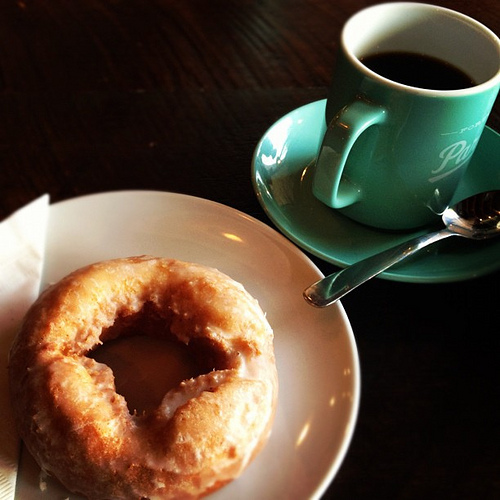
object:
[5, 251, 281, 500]
donut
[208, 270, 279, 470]
glaze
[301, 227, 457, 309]
handle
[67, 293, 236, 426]
hole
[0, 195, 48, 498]
napkin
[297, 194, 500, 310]
spoon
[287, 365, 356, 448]
reflection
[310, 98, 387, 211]
handle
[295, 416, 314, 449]
light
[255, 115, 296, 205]
reflection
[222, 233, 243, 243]
light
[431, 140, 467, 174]
writing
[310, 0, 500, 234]
coffee cup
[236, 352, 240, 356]
bubble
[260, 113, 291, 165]
light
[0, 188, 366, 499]
plate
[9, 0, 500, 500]
table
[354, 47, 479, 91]
coffee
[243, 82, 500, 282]
plate